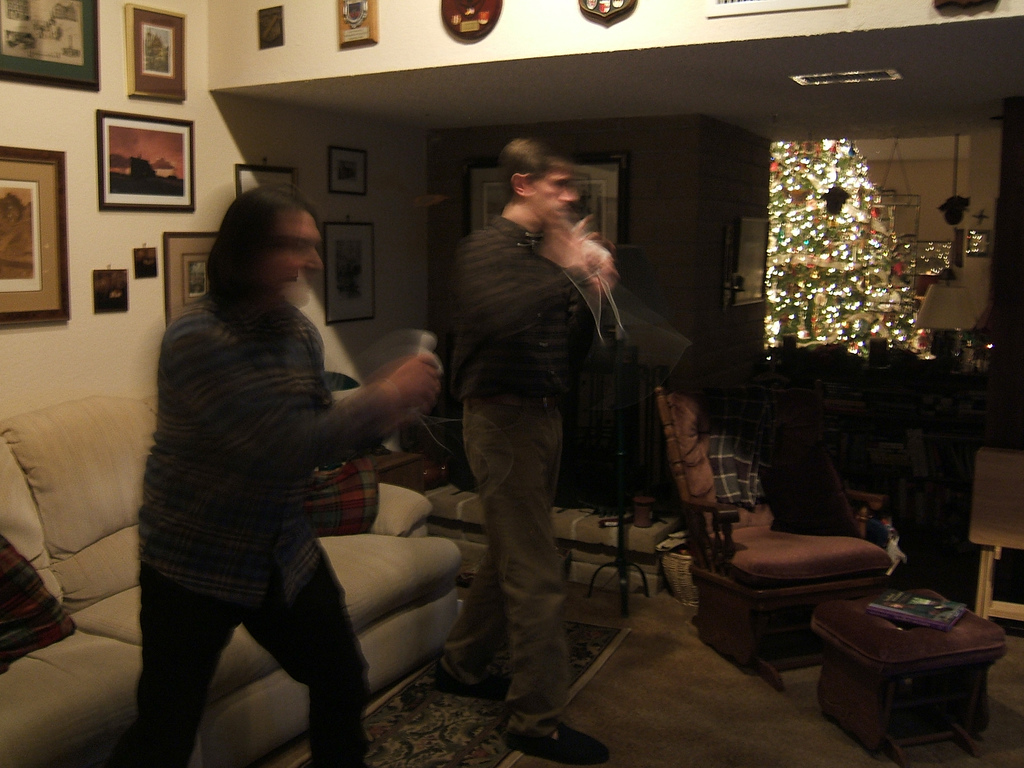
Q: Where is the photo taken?
A: Living room.